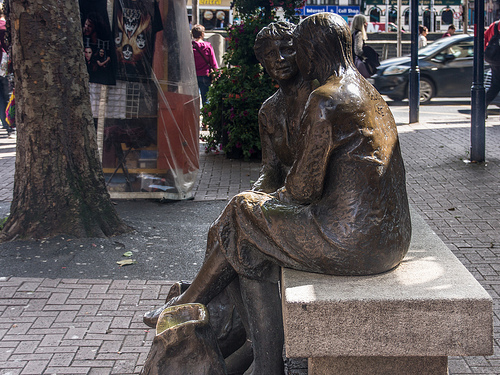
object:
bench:
[279, 201, 494, 375]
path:
[410, 113, 478, 174]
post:
[470, 0, 487, 165]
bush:
[198, 0, 308, 163]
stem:
[246, 11, 265, 18]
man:
[163, 18, 322, 375]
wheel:
[420, 78, 437, 104]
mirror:
[431, 39, 475, 63]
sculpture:
[141, 11, 413, 375]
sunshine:
[317, 10, 349, 28]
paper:
[148, 184, 176, 191]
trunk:
[0, 0, 135, 244]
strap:
[191, 43, 212, 68]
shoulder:
[200, 39, 215, 49]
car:
[366, 32, 500, 104]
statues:
[167, 19, 325, 375]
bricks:
[46, 305, 110, 334]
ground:
[154, 237, 174, 263]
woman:
[190, 24, 220, 131]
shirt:
[191, 41, 222, 78]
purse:
[192, 43, 217, 83]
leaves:
[116, 256, 137, 267]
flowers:
[248, 149, 255, 154]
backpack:
[483, 21, 500, 66]